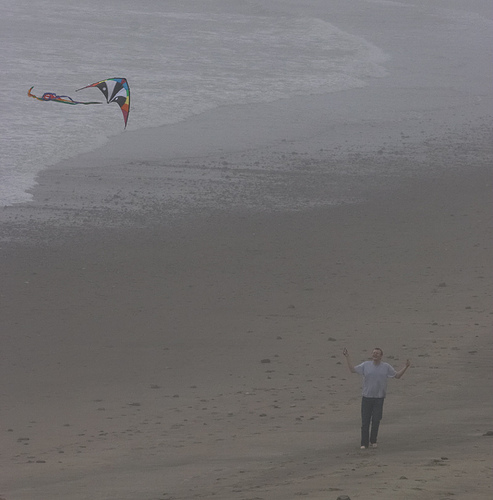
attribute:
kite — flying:
[49, 72, 162, 150]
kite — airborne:
[30, 61, 144, 144]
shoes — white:
[356, 440, 382, 450]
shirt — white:
[354, 359, 402, 396]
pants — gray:
[355, 391, 388, 443]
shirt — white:
[353, 361, 391, 401]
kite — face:
[68, 35, 194, 148]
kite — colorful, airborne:
[0, 39, 158, 159]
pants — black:
[340, 394, 411, 443]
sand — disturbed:
[247, 353, 347, 418]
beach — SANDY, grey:
[0, 2, 491, 497]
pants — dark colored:
[362, 393, 384, 444]